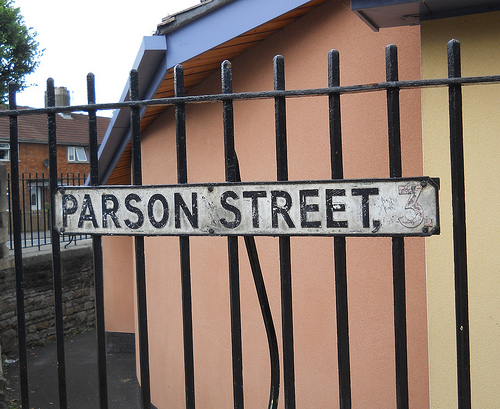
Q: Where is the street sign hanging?
A: On a gate.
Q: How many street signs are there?
A: One.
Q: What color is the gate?
A: Black.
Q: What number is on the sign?
A: Three.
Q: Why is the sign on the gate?
A: So people can see it.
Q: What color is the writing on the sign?
A: Black.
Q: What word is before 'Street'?
A: Parson.